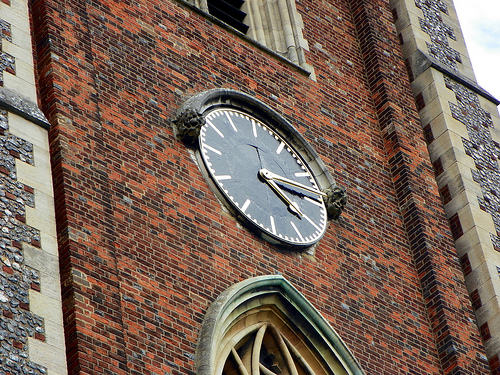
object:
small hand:
[266, 180, 305, 218]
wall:
[359, 12, 493, 143]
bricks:
[401, 340, 477, 372]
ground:
[411, 68, 441, 127]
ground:
[422, 149, 460, 186]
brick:
[312, 86, 389, 128]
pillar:
[390, 0, 499, 375]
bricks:
[35, 124, 236, 358]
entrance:
[196, 282, 363, 375]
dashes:
[181, 74, 331, 251]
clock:
[198, 101, 328, 247]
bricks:
[5, 5, 160, 173]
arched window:
[190, 272, 369, 373]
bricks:
[135, 201, 210, 263]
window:
[176, 0, 321, 77]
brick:
[437, 143, 477, 172]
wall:
[175, 15, 302, 114]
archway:
[193, 274, 367, 374]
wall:
[0, 20, 63, 370]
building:
[0, 0, 500, 370]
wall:
[86, 0, 165, 372]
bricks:
[2, 259, 16, 273]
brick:
[423, 128, 467, 161]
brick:
[378, 111, 425, 139]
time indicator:
[222, 109, 242, 132]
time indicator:
[275, 139, 287, 156]